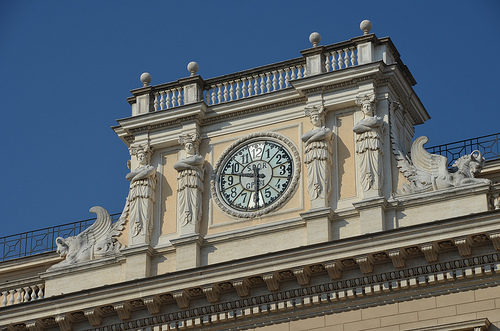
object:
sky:
[3, 4, 498, 248]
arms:
[308, 130, 331, 143]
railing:
[3, 220, 100, 268]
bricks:
[379, 311, 419, 330]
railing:
[413, 128, 499, 167]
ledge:
[123, 18, 395, 98]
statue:
[394, 135, 490, 185]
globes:
[140, 72, 153, 83]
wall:
[0, 15, 497, 330]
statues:
[300, 106, 333, 208]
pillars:
[181, 75, 200, 104]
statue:
[45, 205, 120, 272]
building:
[3, 11, 499, 326]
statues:
[174, 132, 203, 234]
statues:
[126, 145, 155, 243]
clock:
[211, 132, 302, 218]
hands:
[225, 173, 264, 178]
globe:
[359, 20, 372, 32]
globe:
[309, 32, 321, 44]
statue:
[352, 100, 385, 200]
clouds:
[7, 22, 500, 171]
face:
[215, 141, 293, 213]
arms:
[353, 125, 370, 132]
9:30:
[221, 158, 283, 208]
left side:
[107, 57, 255, 147]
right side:
[289, 18, 413, 76]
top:
[69, 38, 483, 235]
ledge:
[137, 196, 495, 291]